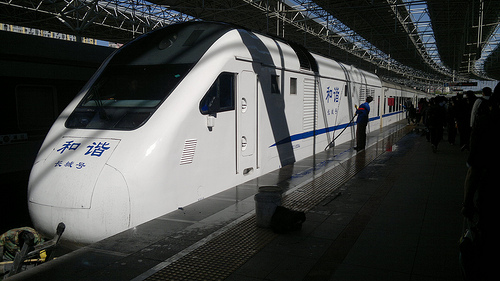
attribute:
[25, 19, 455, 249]
train — long, white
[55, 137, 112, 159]
writing — blue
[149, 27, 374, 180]
beam — metal, steel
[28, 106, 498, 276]
walkway — concrete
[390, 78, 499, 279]
people — waiting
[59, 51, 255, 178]
train — white, long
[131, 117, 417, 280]
line — white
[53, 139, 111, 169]
writing — blue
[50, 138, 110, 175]
writing — Japanese